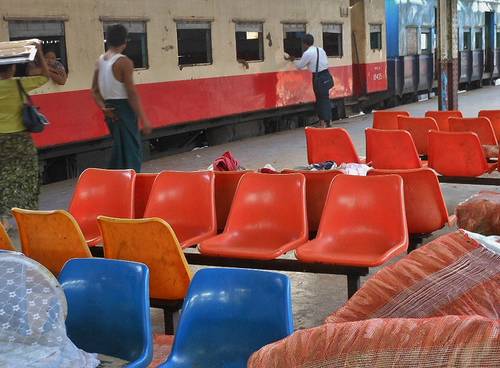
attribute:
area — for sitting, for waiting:
[0, 110, 500, 367]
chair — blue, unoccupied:
[61, 258, 153, 360]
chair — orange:
[10, 206, 96, 278]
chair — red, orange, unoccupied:
[69, 167, 137, 245]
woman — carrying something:
[1, 44, 50, 242]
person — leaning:
[23, 48, 68, 87]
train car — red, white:
[0, 0, 389, 150]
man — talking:
[291, 32, 336, 129]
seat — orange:
[97, 214, 193, 300]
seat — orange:
[11, 207, 93, 275]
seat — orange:
[1, 222, 17, 251]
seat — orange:
[71, 167, 136, 245]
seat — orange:
[145, 171, 218, 247]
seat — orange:
[199, 171, 308, 260]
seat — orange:
[295, 174, 412, 269]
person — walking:
[92, 23, 154, 175]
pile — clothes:
[205, 151, 249, 171]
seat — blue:
[158, 269, 295, 367]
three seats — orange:
[0, 206, 194, 301]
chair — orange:
[1, 223, 13, 253]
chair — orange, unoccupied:
[97, 214, 198, 300]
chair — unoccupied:
[365, 128, 426, 171]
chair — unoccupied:
[428, 128, 499, 176]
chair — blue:
[160, 268, 292, 366]